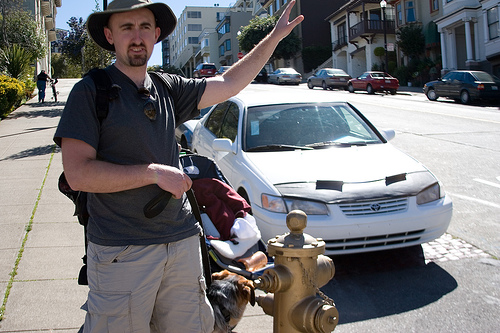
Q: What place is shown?
A: It is a street.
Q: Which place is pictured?
A: It is a street.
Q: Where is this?
A: This is at the street.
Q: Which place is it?
A: It is a street.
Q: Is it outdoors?
A: Yes, it is outdoors.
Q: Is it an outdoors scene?
A: Yes, it is outdoors.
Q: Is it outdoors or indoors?
A: It is outdoors.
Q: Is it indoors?
A: No, it is outdoors.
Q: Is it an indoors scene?
A: No, it is outdoors.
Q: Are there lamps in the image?
A: No, there are no lamps.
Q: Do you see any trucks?
A: No, there are no trucks.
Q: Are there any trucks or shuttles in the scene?
A: No, there are no trucks or shuttles.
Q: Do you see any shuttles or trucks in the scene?
A: No, there are no trucks or shuttles.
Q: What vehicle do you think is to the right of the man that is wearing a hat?
A: The vehicle is a car.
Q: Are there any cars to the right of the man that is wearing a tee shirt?
A: Yes, there is a car to the right of the man.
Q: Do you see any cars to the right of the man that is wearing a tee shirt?
A: Yes, there is a car to the right of the man.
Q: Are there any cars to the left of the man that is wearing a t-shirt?
A: No, the car is to the right of the man.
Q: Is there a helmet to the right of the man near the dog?
A: No, there is a car to the right of the man.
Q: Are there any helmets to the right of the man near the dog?
A: No, there is a car to the right of the man.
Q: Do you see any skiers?
A: No, there are no skiers.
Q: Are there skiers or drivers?
A: No, there are no skiers or drivers.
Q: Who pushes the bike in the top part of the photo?
A: The man pushes the bike.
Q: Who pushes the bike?
A: The man pushes the bike.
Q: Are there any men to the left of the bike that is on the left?
A: Yes, there is a man to the left of the bike.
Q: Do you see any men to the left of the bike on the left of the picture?
A: Yes, there is a man to the left of the bike.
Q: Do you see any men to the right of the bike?
A: No, the man is to the left of the bike.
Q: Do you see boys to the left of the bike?
A: No, there is a man to the left of the bike.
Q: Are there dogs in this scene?
A: Yes, there is a dog.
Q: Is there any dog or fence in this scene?
A: Yes, there is a dog.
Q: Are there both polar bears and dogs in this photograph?
A: No, there is a dog but no polar bears.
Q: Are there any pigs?
A: No, there are no pigs.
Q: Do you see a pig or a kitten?
A: No, there are no pigs or kittens.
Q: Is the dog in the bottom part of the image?
A: Yes, the dog is in the bottom of the image.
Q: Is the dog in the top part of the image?
A: No, the dog is in the bottom of the image.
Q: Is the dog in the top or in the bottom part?
A: The dog is in the bottom of the image.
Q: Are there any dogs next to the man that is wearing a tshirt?
A: Yes, there is a dog next to the man.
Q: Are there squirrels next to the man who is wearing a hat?
A: No, there is a dog next to the man.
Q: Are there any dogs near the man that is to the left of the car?
A: Yes, there is a dog near the man.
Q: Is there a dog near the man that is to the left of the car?
A: Yes, there is a dog near the man.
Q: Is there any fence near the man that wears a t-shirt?
A: No, there is a dog near the man.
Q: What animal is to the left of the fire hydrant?
A: The animal is a dog.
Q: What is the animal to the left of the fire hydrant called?
A: The animal is a dog.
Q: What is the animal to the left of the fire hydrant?
A: The animal is a dog.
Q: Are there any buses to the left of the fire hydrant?
A: No, there is a dog to the left of the fire hydrant.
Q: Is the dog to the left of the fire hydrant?
A: Yes, the dog is to the left of the fire hydrant.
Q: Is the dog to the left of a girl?
A: No, the dog is to the left of the fire hydrant.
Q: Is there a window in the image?
A: Yes, there is a window.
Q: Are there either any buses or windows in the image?
A: Yes, there is a window.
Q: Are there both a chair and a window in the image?
A: No, there is a window but no chairs.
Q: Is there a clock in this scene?
A: No, there are no clocks.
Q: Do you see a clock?
A: No, there are no clocks.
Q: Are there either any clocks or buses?
A: No, there are no clocks or buses.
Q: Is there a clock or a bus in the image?
A: No, there are no clocks or buses.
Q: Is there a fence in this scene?
A: No, there are no fences.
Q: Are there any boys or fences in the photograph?
A: No, there are no fences or boys.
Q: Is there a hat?
A: Yes, there is a hat.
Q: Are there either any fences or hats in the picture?
A: Yes, there is a hat.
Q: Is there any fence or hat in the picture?
A: Yes, there is a hat.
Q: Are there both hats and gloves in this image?
A: No, there is a hat but no gloves.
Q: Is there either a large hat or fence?
A: Yes, there is a large hat.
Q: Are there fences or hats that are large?
A: Yes, the hat is large.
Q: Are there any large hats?
A: Yes, there is a large hat.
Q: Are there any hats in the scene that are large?
A: Yes, there is a hat that is large.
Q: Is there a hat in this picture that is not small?
A: Yes, there is a large hat.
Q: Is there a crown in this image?
A: No, there are no crowns.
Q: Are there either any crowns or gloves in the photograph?
A: No, there are no crowns or gloves.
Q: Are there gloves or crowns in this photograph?
A: No, there are no crowns or gloves.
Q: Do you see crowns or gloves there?
A: No, there are no crowns or gloves.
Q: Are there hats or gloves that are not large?
A: No, there is a hat but it is large.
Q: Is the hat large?
A: Yes, the hat is large.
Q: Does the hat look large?
A: Yes, the hat is large.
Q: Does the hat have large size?
A: Yes, the hat is large.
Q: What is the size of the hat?
A: The hat is large.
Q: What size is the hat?
A: The hat is large.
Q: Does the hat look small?
A: No, the hat is large.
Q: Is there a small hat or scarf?
A: No, there is a hat but it is large.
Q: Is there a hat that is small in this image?
A: No, there is a hat but it is large.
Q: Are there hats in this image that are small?
A: No, there is a hat but it is large.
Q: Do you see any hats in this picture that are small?
A: No, there is a hat but it is large.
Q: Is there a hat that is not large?
A: No, there is a hat but it is large.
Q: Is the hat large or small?
A: The hat is large.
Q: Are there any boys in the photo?
A: No, there are no boys.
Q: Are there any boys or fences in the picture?
A: No, there are no boys or fences.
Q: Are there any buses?
A: No, there are no buses.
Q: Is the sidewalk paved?
A: Yes, the sidewalk is paved.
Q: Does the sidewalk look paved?
A: Yes, the sidewalk is paved.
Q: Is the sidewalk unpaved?
A: No, the sidewalk is paved.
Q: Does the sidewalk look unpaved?
A: No, the sidewalk is paved.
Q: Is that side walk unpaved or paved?
A: The side walk is paved.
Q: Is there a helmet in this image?
A: No, there are no helmets.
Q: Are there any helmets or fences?
A: No, there are no helmets or fences.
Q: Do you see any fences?
A: No, there are no fences.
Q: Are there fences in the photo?
A: No, there are no fences.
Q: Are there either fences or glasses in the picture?
A: No, there are no fences or glasses.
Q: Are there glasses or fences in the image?
A: No, there are no fences or glasses.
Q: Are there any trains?
A: No, there are no trains.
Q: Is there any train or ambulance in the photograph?
A: No, there are no trains or ambulances.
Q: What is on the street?
A: The car is on the street.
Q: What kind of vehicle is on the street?
A: The vehicle is a car.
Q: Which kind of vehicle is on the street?
A: The vehicle is a car.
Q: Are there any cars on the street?
A: Yes, there is a car on the street.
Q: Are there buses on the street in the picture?
A: No, there is a car on the street.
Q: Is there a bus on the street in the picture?
A: No, there is a car on the street.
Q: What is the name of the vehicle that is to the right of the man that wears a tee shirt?
A: The vehicle is a car.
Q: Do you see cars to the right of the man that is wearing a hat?
A: Yes, there is a car to the right of the man.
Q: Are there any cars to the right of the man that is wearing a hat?
A: Yes, there is a car to the right of the man.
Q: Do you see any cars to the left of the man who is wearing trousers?
A: No, the car is to the right of the man.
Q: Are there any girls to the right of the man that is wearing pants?
A: No, there is a car to the right of the man.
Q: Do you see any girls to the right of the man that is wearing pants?
A: No, there is a car to the right of the man.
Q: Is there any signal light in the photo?
A: No, there are no traffic lights.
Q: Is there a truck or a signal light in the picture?
A: No, there are no traffic lights or trucks.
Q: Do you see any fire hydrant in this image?
A: Yes, there is a fire hydrant.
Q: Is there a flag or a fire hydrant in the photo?
A: Yes, there is a fire hydrant.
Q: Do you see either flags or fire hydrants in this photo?
A: Yes, there is a fire hydrant.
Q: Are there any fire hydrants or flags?
A: Yes, there is a fire hydrant.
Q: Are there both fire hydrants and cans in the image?
A: No, there is a fire hydrant but no cans.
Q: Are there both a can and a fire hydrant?
A: No, there is a fire hydrant but no cans.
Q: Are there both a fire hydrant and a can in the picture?
A: No, there is a fire hydrant but no cans.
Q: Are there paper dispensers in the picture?
A: No, there are no paper dispensers.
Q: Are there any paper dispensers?
A: No, there are no paper dispensers.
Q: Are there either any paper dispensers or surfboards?
A: No, there are no paper dispensers or surfboards.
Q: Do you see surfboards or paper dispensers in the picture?
A: No, there are no paper dispensers or surfboards.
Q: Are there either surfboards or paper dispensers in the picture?
A: No, there are no paper dispensers or surfboards.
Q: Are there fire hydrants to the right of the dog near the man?
A: Yes, there is a fire hydrant to the right of the dog.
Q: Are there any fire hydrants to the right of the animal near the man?
A: Yes, there is a fire hydrant to the right of the dog.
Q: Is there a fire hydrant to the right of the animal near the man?
A: Yes, there is a fire hydrant to the right of the dog.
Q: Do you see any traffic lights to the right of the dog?
A: No, there is a fire hydrant to the right of the dog.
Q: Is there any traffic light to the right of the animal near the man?
A: No, there is a fire hydrant to the right of the dog.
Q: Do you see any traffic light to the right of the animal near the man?
A: No, there is a fire hydrant to the right of the dog.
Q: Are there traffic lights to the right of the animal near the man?
A: No, there is a fire hydrant to the right of the dog.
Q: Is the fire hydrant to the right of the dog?
A: Yes, the fire hydrant is to the right of the dog.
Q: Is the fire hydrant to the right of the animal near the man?
A: Yes, the fire hydrant is to the right of the dog.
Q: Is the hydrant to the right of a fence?
A: No, the hydrant is to the right of the dog.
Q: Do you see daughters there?
A: No, there are no daughters.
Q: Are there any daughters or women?
A: No, there are no daughters or women.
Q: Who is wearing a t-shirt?
A: The man is wearing a t-shirt.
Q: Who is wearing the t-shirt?
A: The man is wearing a t-shirt.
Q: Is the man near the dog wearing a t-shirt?
A: Yes, the man is wearing a t-shirt.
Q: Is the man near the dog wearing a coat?
A: No, the man is wearing a t-shirt.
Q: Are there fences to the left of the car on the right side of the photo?
A: No, there is a man to the left of the car.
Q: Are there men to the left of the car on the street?
A: Yes, there is a man to the left of the car.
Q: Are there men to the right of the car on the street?
A: No, the man is to the left of the car.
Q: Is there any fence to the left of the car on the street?
A: No, there is a man to the left of the car.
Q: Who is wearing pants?
A: The man is wearing pants.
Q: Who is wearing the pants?
A: The man is wearing pants.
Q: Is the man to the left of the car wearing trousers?
A: Yes, the man is wearing trousers.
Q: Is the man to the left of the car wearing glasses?
A: No, the man is wearing trousers.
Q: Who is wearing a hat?
A: The man is wearing a hat.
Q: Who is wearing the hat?
A: The man is wearing a hat.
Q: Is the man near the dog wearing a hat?
A: Yes, the man is wearing a hat.